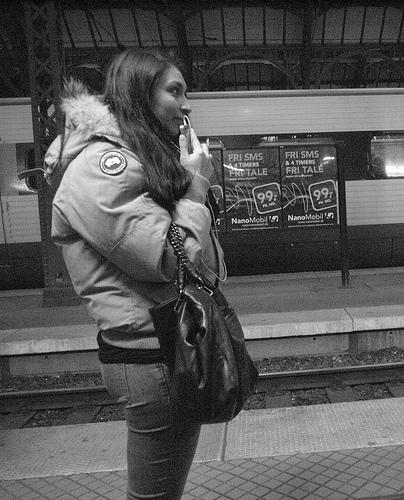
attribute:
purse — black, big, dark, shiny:
[130, 230, 260, 435]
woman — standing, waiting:
[74, 61, 234, 357]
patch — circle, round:
[96, 151, 134, 187]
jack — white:
[204, 193, 237, 297]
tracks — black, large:
[272, 360, 402, 406]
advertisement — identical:
[212, 133, 346, 229]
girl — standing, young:
[55, 50, 216, 278]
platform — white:
[17, 273, 402, 368]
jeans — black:
[95, 361, 199, 493]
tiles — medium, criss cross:
[243, 469, 361, 496]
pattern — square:
[272, 469, 295, 485]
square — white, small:
[107, 157, 118, 169]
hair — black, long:
[99, 43, 164, 148]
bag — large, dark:
[153, 283, 257, 428]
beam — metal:
[23, 10, 73, 297]